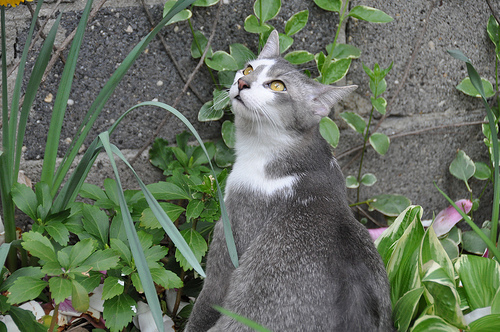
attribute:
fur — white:
[220, 83, 295, 199]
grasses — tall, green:
[4, 1, 239, 329]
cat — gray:
[195, 25, 397, 330]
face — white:
[224, 32, 361, 124]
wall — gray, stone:
[370, 5, 456, 182]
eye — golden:
[262, 78, 287, 95]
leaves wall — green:
[432, 46, 494, 163]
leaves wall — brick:
[6, 109, 186, 321]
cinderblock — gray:
[2, 0, 496, 221]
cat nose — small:
[235, 77, 250, 94]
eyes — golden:
[261, 77, 302, 89]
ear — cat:
[307, 82, 362, 107]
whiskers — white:
[214, 87, 276, 134]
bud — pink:
[432, 197, 477, 237]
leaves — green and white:
[447, 143, 489, 190]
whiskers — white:
[259, 104, 289, 131]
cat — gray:
[182, 36, 418, 330]